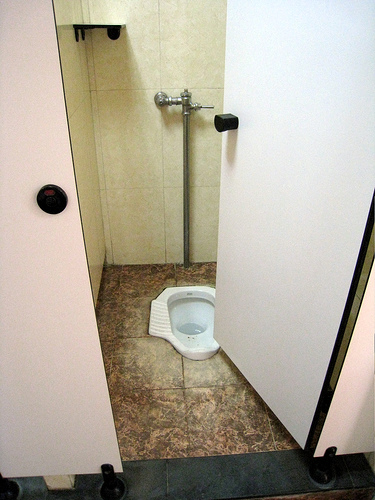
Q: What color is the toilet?
A: White.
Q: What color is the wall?
A: White.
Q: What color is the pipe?
A: Silver.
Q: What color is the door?
A: White.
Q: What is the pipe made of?
A: Metal.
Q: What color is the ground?
A: Brown.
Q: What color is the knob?
A: Black.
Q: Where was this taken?
A: Bathroom.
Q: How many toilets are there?
A: 1.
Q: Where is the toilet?
A: In the floor.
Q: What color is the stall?
A: White.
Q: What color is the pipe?
A: Silver.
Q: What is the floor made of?
A: Tile.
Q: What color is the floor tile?
A: Brown.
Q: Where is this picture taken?
A: A bathroom.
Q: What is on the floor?
A: A toilet.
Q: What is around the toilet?
A: Tile.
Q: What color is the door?
A: White.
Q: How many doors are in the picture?
A: One.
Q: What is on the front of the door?
A: A handle.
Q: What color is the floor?
A: Brown.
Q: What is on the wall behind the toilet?
A: A metal pipe.